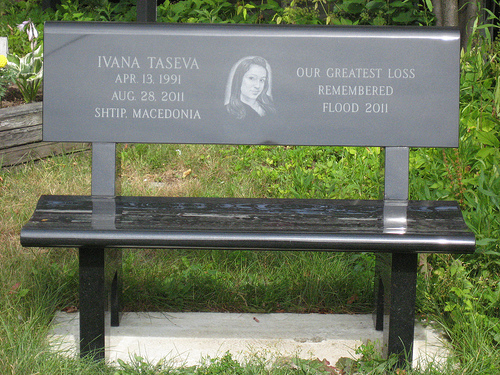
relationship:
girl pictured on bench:
[220, 51, 278, 128] [18, 18, 478, 373]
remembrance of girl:
[88, 45, 427, 133] [219, 50, 278, 121]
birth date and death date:
[112, 64, 186, 92] [107, 84, 190, 105]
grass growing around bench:
[0, 247, 497, 371] [18, 18, 478, 373]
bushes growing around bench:
[7, 2, 498, 42] [18, 18, 478, 373]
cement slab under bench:
[29, 298, 469, 373] [18, 18, 478, 373]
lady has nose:
[223, 49, 281, 134] [253, 78, 263, 96]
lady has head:
[222, 50, 281, 127] [236, 54, 270, 114]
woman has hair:
[218, 54, 275, 119] [227, 53, 285, 125]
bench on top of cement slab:
[32, 10, 497, 323] [39, 298, 468, 373]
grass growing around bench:
[2, 62, 496, 373] [18, 18, 478, 373]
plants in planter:
[0, 11, 47, 105] [2, 83, 107, 168]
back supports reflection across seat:
[381, 141, 416, 201] [22, 180, 492, 252]